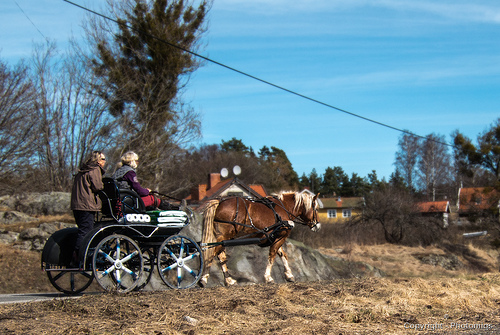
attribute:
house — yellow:
[294, 176, 383, 238]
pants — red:
[131, 190, 173, 215]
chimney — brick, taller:
[197, 159, 245, 194]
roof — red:
[448, 175, 492, 227]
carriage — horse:
[37, 184, 204, 294]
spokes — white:
[96, 249, 142, 276]